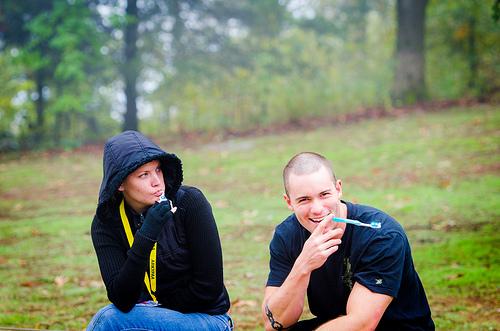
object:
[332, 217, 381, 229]
tooth brush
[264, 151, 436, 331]
man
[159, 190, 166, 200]
tooth brush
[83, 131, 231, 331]
girl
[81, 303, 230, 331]
pants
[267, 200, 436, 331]
tee shirt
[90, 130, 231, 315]
coat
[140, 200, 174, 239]
gloves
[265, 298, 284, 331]
tattoo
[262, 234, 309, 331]
arm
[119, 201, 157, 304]
lanyard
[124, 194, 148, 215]
neck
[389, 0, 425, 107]
tree trunk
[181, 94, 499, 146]
leaves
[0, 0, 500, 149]
tree line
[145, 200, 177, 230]
hand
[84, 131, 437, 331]
two people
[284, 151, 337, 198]
hair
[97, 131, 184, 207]
hood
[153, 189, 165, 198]
mouth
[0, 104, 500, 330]
ground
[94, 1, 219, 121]
sky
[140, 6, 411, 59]
branches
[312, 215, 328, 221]
teeth